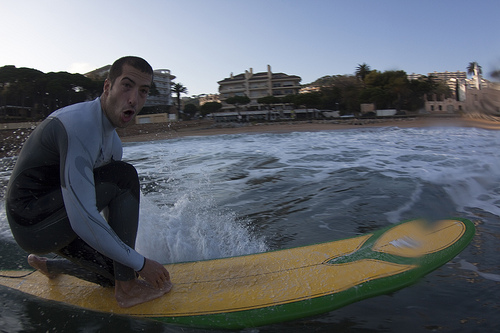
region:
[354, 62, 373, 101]
a distant palm tree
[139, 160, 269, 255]
a spray of ocean water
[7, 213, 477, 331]
a green and yellow surfboard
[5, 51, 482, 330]
a man surfing a wave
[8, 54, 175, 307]
a man wearing a wetsuit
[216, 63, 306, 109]
a distant beige house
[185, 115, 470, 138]
a sand covered beach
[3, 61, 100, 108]
a row of trees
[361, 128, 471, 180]
a large amount of bubbles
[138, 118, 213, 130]
a pile of rocks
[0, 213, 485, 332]
a yellow and green surf board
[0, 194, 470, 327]
water all over a surf board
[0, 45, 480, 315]
a guy posing for a picture on a surf board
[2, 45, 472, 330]
a guy surfing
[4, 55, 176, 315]
a guy in a grey wet suite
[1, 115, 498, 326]
Ocean water foam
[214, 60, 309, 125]
a multi level building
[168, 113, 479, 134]
a strip of beach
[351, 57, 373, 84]
the top of a tall palm tree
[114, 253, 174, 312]
a surfer's foot and hand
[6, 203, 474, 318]
the surfboard is green and yellow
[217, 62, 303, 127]
the hotel is tall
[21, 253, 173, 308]
the man's feet are on the surfboard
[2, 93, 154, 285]
the wet suit is white and gray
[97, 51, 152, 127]
the man's hair is short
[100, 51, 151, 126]
the man's mouth is open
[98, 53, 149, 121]
the man has dark hair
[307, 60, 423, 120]
trees beside the hotel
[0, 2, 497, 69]
the sky is clear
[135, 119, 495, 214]
the water is foamy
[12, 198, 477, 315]
The surfboard is yellow and green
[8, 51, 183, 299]
The man is riding the surfboard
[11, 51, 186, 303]
The surfer is crouching on the surfboard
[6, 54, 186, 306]
The surfer is wearing a wetsuit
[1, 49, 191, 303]
The wet suit is blue and black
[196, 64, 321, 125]
House on the beach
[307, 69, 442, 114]
Trees on the beach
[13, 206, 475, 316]
The surfboard is in the water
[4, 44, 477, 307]
The man is surfing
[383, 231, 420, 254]
White sticker on surf board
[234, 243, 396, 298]
surfboard is yellow and green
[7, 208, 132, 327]
man is kneeling on the surfboard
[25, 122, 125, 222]
man is wearing a wetsuit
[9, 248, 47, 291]
safety cord next to surfer's ankle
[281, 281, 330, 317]
surfboard is outlined in green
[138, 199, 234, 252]
splashing next to the surfboard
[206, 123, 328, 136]
sand along the shore line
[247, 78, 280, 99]
balcony on the building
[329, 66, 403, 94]
trees behind the beach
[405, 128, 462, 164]
white foam on the water